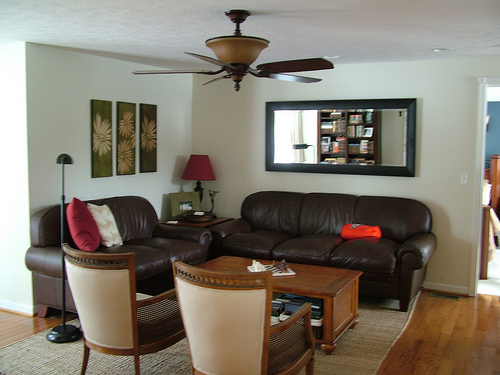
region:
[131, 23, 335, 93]
Ceiling fan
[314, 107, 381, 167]
Books on a book shelf reflected in the mirror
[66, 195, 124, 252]
Pillows on the sofa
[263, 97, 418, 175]
Framed mirror over the sofa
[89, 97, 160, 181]
Flower prints on the wall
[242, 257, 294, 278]
Chess game set up on the coffee table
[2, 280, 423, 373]
Rug on the floor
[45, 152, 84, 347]
Black floor lamp by the sofa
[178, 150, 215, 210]
Lamp on the end table in the corner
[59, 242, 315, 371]
Two chairs in front of the coffee table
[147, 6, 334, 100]
a large brown ceiling fan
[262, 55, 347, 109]
the blades of a fan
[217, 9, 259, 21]
the base of a fan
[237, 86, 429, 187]
a long and black mirror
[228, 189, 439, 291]
a black leather couch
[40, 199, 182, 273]
a small black love seat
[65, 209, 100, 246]
a large red throw pillow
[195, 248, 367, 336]
a small brown coffee table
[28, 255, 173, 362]
a small brown and tan chair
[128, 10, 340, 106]
fan attached to the ceiling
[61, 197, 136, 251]
two pillows on the couch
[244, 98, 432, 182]
mirror on the wall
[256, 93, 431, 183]
reflection in the mirror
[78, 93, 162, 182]
three wall decorations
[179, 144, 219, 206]
red shade on the lamp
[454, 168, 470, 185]
light switch on the wall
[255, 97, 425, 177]
black frame around the mirror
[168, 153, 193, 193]
shadow from the lamp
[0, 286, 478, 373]
rug on the hardwood floor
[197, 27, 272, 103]
A light on a ceiling fan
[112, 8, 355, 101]
a ceiling fan on a ceiling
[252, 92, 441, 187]
a large mirror on a wall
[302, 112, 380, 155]
the reflection of a bookshelf in a mirror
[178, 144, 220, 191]
a red lamp shade on a lamp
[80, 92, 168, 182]
three paintings of flowers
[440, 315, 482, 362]
a brown hardwood floor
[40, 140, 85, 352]
a tall metal floor lamp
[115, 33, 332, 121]
fan on the ceiling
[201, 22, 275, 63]
light shade from ceiling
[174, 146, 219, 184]
red lamp shade on lamp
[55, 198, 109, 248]
red pillow on couch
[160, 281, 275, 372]
white back of chair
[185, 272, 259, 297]
brown boarder of chair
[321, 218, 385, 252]
orange pillow on couch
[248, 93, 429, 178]
large mirror on side of wall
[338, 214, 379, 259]
a pillow on the couch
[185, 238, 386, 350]
a brown coffee table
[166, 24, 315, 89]
a ceiling fan on the ceiling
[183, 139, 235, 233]
a lamp on the night stand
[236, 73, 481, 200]
a mirror on the wall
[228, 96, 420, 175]
a mirror is framed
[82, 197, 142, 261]
a pillow on the couch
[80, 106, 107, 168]
a picture ont he wall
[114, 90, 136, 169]
a picture on te wall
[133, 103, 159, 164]
a picture on the wall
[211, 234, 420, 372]
a wooden coffee table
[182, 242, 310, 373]
a wooden cahir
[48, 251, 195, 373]
a wooden chair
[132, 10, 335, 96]
Wooden ceiling fan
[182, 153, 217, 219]
Red table lamp